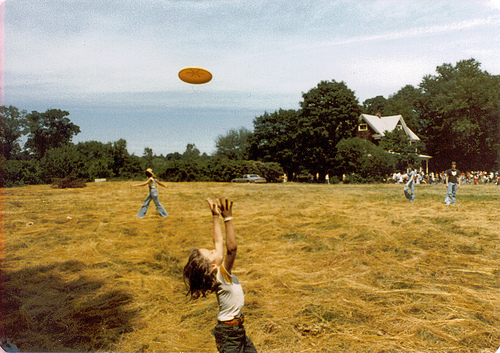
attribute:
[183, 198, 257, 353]
child — innocent, a girl, standing, small, sweet, cute, little, girl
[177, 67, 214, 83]
frisbee — yellow, orange, in the air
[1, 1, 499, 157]
sky — cloudy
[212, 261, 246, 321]
shirt — white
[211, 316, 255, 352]
shorts — green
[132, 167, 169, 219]
woman — walking alone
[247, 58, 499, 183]
trees — tall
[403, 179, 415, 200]
jeans — blue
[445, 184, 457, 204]
jeans — blue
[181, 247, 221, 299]
hair — brown, blond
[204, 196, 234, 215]
hands — up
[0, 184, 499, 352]
grass — brown